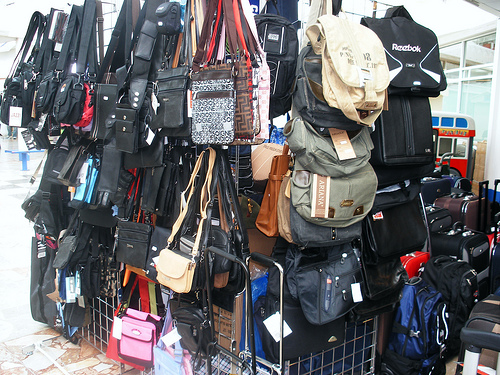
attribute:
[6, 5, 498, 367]
bags — displayed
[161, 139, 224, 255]
strap — long, tan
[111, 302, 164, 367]
bag — pink, purple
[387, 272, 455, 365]
backpack — black, blue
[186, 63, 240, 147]
design — blue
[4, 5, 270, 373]
purse — on display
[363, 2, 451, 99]
bag — black, white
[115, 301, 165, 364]
purse — pink, black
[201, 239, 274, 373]
cart — black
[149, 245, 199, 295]
purse — small, tan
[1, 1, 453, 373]
purses — displayed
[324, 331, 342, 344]
logo — metal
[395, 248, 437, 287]
suitcase — red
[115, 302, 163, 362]
bag — pink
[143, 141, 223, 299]
purse — tan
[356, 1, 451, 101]
bag — black, white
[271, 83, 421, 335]
backpack — blue , black 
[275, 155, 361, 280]
print — white 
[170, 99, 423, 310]
bag — black , Blue 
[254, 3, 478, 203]
rack — Black 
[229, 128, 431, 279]
bag — Black 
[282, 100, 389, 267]
bag — Tan 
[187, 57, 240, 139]
bag — Tan 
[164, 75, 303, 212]
bag — Black 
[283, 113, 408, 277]
bag — white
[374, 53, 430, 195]
bag — black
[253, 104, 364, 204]
bag — green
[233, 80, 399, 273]
bag — blue , black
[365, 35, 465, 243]
bag — brown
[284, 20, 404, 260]
bag — gray , white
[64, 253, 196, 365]
bag — pink , black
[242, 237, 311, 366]
stripe — brown 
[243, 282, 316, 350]
tag — white 